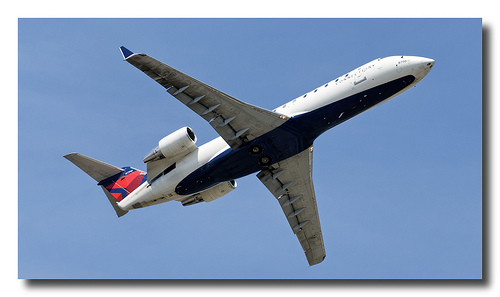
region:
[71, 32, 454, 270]
this is an airplane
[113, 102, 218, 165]
this is the right engine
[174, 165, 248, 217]
this is the left engine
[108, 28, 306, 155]
this is the right wing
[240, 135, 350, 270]
this is the left wing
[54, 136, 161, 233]
this is the tail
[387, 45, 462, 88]
this is the nose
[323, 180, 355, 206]
this is the sky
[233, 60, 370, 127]
these are plane windows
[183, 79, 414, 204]
this is the bottom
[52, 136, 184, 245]
the tail of the airplane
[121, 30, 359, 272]
the white wings of the airplane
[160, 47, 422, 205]
blue underbelly on the plane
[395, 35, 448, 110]
the nose of the airplane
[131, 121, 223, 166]
engine in the back of the plane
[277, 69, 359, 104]
windows on the plane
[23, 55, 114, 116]
a blue sky behind the plane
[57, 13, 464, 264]
a white airplane in the sky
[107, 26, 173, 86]
bent wing of the airplane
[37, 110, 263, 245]
the tail end of the air plane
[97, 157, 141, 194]
The red and blue design on the tail of the plane.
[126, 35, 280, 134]
The left side wing of the plane.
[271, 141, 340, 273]
The right side wing of the plane.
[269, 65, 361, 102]
The passenger windows on the side of the plane.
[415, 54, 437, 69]
The nose of the plane.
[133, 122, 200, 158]
The left side engine.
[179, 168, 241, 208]
The right side engine.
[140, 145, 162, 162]
The silver ending on the left side engine.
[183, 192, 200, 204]
The silver tip on the right side engine.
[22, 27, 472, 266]
The blue sky above the plane.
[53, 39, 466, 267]
Airplane in a clear blue sky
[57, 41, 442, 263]
Passenger plane in the air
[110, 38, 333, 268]
Underside of airplane wings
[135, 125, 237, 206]
Two engines on an airplane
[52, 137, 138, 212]
Tail of a passenger airplane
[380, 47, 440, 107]
Nose of a passenger airplane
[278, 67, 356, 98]
Row of windows in an airplane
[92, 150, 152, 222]
Red, white, and blue paint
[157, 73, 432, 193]
Blue and white paint on the underside of a plane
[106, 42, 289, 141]
One wing of an airplane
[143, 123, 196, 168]
the engine of an airliner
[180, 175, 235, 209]
the engine of a commercial airplane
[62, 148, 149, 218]
the tail of an airplane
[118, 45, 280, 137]
the underside of an airplane wing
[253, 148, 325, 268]
the underside of an airplane wing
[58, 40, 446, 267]
an airplane in flight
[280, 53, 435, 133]
the fuselage of an airplane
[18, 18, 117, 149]
a patch of clear sky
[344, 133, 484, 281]
a bright blue sky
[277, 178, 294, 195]
a fuel tank on a plane wing